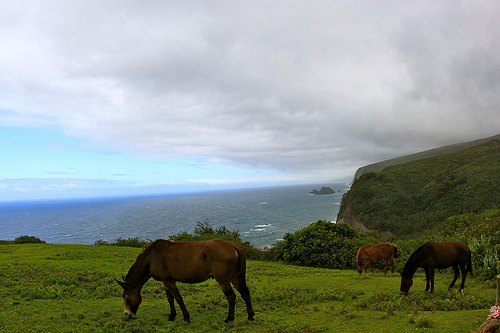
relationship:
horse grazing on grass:
[399, 239, 475, 294] [0, 242, 500, 332]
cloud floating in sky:
[1, 0, 499, 184] [1, 0, 500, 202]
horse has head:
[399, 239, 475, 294] [399, 270, 414, 295]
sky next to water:
[1, 0, 500, 202] [0, 180, 351, 248]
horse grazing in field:
[114, 237, 257, 322] [1, 243, 500, 331]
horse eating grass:
[354, 240, 399, 276] [0, 242, 500, 332]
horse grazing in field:
[399, 239, 475, 294] [1, 243, 500, 331]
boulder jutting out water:
[310, 185, 334, 195] [0, 180, 351, 248]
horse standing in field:
[114, 237, 257, 322] [1, 243, 500, 331]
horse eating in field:
[399, 239, 475, 294] [1, 243, 500, 331]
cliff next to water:
[334, 134, 499, 243] [0, 180, 351, 248]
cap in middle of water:
[254, 222, 270, 228] [0, 180, 351, 248]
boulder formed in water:
[310, 185, 334, 195] [0, 180, 351, 248]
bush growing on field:
[280, 218, 365, 269] [1, 243, 500, 331]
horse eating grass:
[399, 239, 475, 294] [0, 242, 500, 332]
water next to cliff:
[0, 180, 351, 248] [334, 134, 499, 243]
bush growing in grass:
[280, 218, 365, 269] [0, 242, 500, 332]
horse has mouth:
[114, 237, 257, 322] [123, 308, 136, 318]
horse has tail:
[399, 239, 475, 294] [467, 249, 474, 276]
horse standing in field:
[399, 239, 475, 294] [1, 243, 500, 331]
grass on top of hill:
[0, 242, 500, 332] [1, 207, 499, 332]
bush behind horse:
[280, 218, 365, 269] [354, 240, 399, 276]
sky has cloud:
[1, 0, 500, 202] [1, 0, 499, 184]